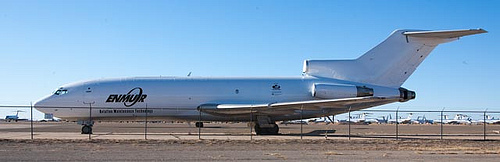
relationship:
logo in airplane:
[104, 87, 148, 107] [30, 27, 488, 135]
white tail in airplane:
[301, 25, 486, 88] [30, 27, 488, 135]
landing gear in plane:
[77, 120, 96, 147] [23, 28, 490, 120]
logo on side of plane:
[98, 82, 151, 107] [37, 20, 488, 140]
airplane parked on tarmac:
[30, 27, 488, 135] [4, 111, 495, 158]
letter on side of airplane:
[96, 101, 161, 122] [30, 27, 488, 135]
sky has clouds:
[3, 6, 498, 123] [191, 41, 281, 76]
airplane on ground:
[30, 27, 488, 135] [3, 120, 498, 160]